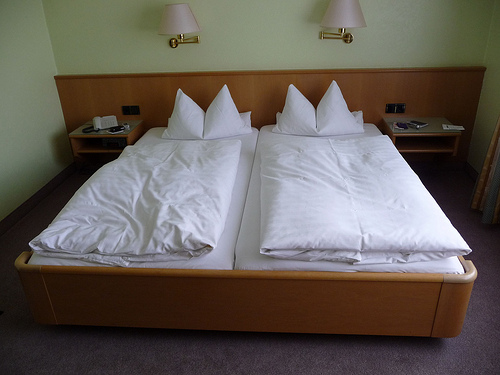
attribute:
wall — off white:
[1, 1, 500, 222]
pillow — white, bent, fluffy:
[162, 83, 253, 143]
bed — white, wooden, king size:
[15, 124, 477, 339]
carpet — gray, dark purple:
[1, 160, 497, 374]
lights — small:
[156, 1, 367, 49]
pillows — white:
[162, 79, 366, 141]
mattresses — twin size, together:
[28, 123, 467, 273]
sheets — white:
[28, 122, 469, 274]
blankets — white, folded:
[29, 135, 473, 267]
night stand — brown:
[67, 118, 147, 171]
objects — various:
[82, 114, 132, 136]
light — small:
[157, 3, 203, 49]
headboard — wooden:
[52, 65, 486, 165]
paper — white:
[440, 122, 466, 131]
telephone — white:
[90, 112, 119, 130]